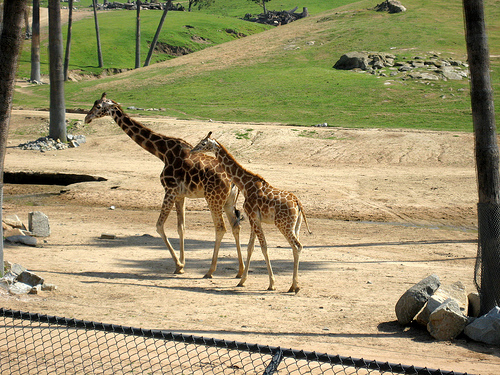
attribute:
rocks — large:
[391, 272, 498, 351]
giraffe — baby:
[189, 131, 309, 288]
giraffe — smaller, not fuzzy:
[182, 120, 317, 309]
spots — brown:
[172, 157, 209, 184]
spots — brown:
[249, 185, 279, 213]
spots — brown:
[114, 109, 193, 169]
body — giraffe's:
[77, 88, 234, 282]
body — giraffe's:
[187, 129, 329, 304]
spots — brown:
[173, 157, 197, 176]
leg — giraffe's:
[202, 200, 226, 281]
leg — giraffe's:
[152, 187, 187, 277]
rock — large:
[23, 213, 53, 244]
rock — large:
[397, 280, 498, 350]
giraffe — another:
[84, 90, 253, 282]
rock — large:
[391, 274, 442, 324]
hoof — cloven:
[235, 281, 248, 290]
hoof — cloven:
[266, 280, 280, 291]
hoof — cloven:
[288, 286, 294, 293]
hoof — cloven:
[293, 286, 301, 296]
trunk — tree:
[44, 3, 72, 147]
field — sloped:
[37, 5, 498, 141]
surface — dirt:
[16, 166, 491, 367]